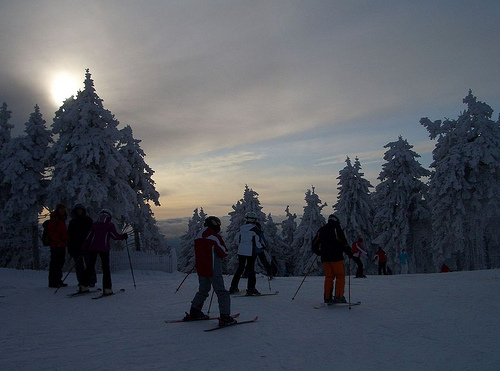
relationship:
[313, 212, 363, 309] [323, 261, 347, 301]
person in red pants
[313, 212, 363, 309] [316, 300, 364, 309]
person on two skis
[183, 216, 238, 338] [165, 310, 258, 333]
person on two skis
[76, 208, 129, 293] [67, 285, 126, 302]
person on two skis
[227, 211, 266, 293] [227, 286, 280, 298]
person on two skis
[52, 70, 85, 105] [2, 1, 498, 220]
sun in sky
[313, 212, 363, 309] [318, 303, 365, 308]
person on skis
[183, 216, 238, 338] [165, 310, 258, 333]
person on skis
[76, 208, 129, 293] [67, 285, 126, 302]
person on skis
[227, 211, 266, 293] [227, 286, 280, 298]
person on skis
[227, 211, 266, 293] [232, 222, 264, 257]
person in white coat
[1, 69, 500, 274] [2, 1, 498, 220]
trees against sky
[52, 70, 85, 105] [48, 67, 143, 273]
sun behind tree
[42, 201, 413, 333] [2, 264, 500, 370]
people in snow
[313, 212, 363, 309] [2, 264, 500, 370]
person on skis in snow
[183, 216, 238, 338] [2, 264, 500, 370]
person on skis in snow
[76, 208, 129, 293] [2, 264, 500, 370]
person on skis in snow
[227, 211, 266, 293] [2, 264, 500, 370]
person on skis in snow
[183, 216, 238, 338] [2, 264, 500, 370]
person in snow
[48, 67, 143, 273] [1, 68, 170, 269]
tree covered in snow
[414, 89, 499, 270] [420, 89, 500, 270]
tree covered in snow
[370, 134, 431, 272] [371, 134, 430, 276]
tree covered in snow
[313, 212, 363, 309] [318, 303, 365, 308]
person wearing skis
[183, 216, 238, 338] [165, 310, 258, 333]
person wearing skis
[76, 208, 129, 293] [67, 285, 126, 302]
person wearing skis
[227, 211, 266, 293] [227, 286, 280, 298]
person wearing skis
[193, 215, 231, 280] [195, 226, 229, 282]
skier with red jacket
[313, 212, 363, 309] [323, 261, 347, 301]
person with orange pants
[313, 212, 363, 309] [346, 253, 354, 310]
person with ski pole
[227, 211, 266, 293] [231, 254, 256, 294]
person in black pants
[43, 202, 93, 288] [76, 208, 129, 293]
two people watching person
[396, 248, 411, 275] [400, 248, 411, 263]
person in blue jacket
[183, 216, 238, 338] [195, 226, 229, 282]
person with red jacket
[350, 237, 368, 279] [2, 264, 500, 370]
person snowboarding down slope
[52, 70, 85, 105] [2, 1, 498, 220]
sun setting in sky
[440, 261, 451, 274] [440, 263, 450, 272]
torso of skiier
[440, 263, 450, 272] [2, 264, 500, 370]
skiier going down slope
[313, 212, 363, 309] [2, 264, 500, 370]
person on snow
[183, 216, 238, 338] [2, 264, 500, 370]
person on snow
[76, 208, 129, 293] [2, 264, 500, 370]
person on snow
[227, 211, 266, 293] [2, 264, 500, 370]
person on snow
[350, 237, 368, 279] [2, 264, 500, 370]
person on snow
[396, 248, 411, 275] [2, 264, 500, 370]
person on snow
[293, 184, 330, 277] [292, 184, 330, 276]
tree covered in snow